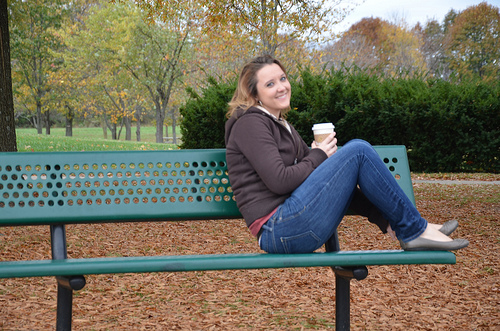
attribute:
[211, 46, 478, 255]
woman — smiling, cute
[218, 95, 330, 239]
sweater — brown, gray, hooded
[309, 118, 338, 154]
cup — paper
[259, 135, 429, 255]
jeans — blue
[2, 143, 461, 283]
bench — green, clean, long, metal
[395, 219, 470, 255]
flats — gray, pair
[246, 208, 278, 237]
shirt — red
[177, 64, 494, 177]
bushes — green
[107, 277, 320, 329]
leaves — scattered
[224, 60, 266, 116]
hair — long, brown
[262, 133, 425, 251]
legs — bent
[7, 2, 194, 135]
trees — distant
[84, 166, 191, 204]
holes — small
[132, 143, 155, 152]
leaves — brown